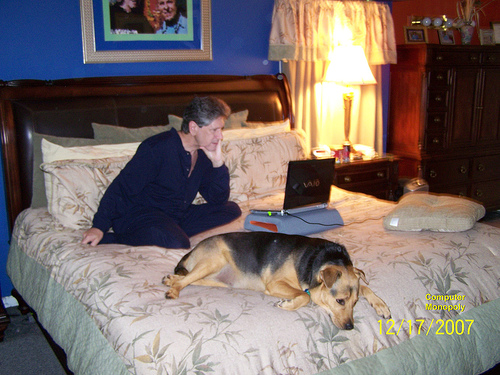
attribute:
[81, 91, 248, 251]
man — sitting, gray, wearing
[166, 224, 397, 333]
dog — laying, black, brown, tan, awake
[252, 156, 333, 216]
laptop — black, resting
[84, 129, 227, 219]
pajamas — blue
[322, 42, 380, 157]
lamp — on, bright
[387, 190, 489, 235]
cushion — square, white, hanging, end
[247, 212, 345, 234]
stand — blue, gray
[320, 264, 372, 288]
ears — floppy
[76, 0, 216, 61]
picture — framed, gold, hanging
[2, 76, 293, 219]
frame — brown, wood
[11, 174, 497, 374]
bed — flowery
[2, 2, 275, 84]
wall — blue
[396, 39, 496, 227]
armoire — wood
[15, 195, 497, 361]
valence — floral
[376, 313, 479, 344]
date — 12/17/2007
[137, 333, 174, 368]
pattern — leaf